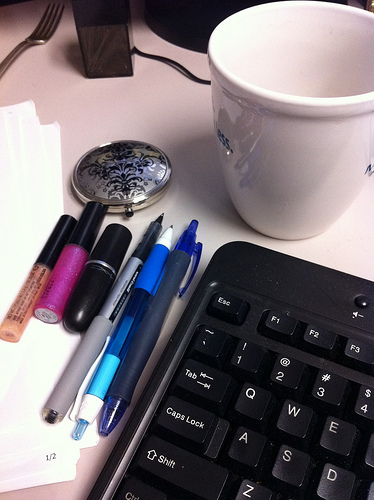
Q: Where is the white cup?
A: On desktop.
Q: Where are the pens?
A: To the left of the keyboard.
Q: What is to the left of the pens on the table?
A: Lipstick and nail polish.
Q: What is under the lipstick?
A: Papers.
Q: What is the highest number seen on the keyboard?
A: 4.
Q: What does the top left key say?
A: Esc.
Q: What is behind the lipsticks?
A: A silver circular object.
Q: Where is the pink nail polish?
A: Between the two lipsticks.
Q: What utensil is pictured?
A: A fork.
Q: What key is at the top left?
A: Escape.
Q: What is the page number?
A: 1.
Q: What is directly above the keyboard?
A: A mug.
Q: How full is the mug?
A: Empty.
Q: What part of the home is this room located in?
A: Office.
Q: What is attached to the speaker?
A: A cord.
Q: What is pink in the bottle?
A: The nail polish.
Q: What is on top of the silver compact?
A: A design.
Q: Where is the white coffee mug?
A: On the table.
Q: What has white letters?
A: Black keyboard.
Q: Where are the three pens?
A: Next to keyboard.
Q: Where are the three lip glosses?
A: On table.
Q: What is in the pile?
A: Paperwork.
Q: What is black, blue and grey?
A: Pens.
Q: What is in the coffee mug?
A: Empty.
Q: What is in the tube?
A: Peach lip gloss.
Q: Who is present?
A: No one.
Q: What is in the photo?
A: Keyboard.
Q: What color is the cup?
A: White.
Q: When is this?
A: Daytime.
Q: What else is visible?
A: Pens.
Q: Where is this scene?
A: At a desk.